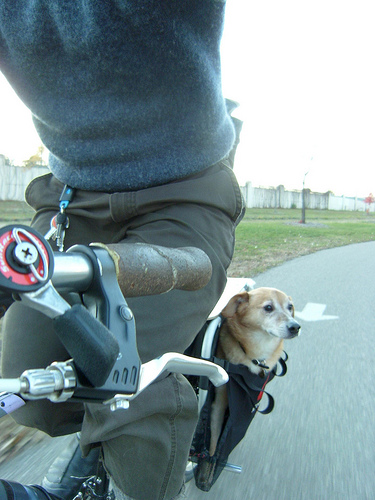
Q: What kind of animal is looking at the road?
A: A dog.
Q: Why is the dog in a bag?
A: Riding on owner's motorcycle.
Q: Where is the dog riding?
A: Slung over back motorcycle.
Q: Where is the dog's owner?
A: Steering the motorcycle.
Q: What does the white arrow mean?
A: Direction to take.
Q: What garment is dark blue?
A: The biker's sweater.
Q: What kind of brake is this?
A: Hand brake.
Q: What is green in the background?
A: Grass.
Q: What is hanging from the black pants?
A: Set of keys.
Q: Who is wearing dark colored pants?
A: The person.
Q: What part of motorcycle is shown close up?
A: Handle.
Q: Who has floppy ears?
A: Dog.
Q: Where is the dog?
A: In bag.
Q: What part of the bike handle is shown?
A: Brake.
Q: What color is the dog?
A: Brown and white.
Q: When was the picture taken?
A: Daytime.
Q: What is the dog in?
A: A bag.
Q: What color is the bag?
A: Black.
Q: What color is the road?
A: Gray.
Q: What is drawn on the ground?
A: An arrow.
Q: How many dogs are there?
A: One.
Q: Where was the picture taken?
A: In the road.